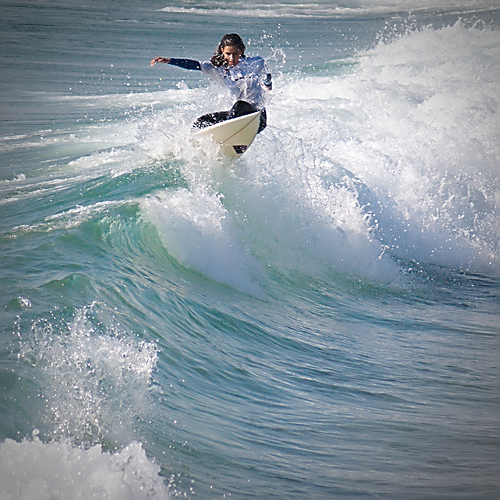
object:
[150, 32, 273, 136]
person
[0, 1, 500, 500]
water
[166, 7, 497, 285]
wave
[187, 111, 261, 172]
surfboard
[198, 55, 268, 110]
shirt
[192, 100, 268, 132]
pants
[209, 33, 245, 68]
hair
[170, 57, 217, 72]
arm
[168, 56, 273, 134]
wetsuit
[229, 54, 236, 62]
nose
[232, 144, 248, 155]
symbol